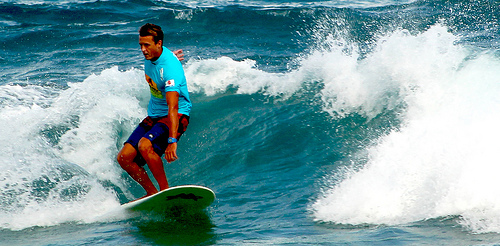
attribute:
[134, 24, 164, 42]
hair — brown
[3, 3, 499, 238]
water — bright blue 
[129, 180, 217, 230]
surfboard — white 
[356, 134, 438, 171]
ground — blue 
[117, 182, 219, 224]
surfboard — large , long, white 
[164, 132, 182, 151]
watch — small , blue 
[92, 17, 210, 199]
man — brown haired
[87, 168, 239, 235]
surfboard — long , green 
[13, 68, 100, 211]
wave — large , crashing , white 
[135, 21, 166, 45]
hair — short 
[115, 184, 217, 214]
surfboard — white 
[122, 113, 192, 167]
trunks — blue , red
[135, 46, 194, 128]
shirt — blue , cotton 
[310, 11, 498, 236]
wave foam — frothy , white 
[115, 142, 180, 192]
legs — long , tan 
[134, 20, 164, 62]
head — small  , tan  , human  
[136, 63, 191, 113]
shirt — light blue 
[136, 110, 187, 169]
shorts — red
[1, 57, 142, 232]
wave — white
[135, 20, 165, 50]
hair — brown